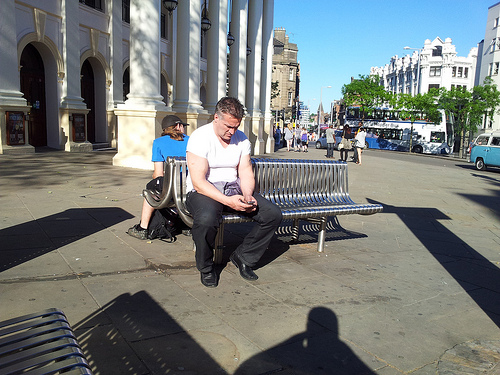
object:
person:
[128, 115, 191, 240]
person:
[338, 122, 351, 162]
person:
[324, 124, 338, 158]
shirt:
[183, 123, 249, 192]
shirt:
[151, 132, 190, 162]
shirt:
[354, 131, 367, 147]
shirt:
[324, 127, 335, 143]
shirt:
[301, 133, 307, 141]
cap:
[161, 114, 189, 126]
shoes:
[198, 262, 220, 288]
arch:
[16, 37, 64, 76]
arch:
[79, 54, 110, 83]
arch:
[122, 65, 135, 94]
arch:
[158, 70, 170, 102]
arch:
[197, 84, 209, 103]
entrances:
[78, 55, 108, 150]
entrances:
[121, 64, 134, 106]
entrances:
[159, 70, 169, 110]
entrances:
[199, 85, 209, 112]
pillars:
[114, 0, 177, 172]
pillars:
[166, 0, 204, 104]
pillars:
[204, 0, 232, 108]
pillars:
[227, 0, 252, 143]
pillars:
[251, 0, 265, 156]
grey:
[297, 193, 322, 204]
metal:
[314, 187, 339, 200]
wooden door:
[20, 49, 51, 150]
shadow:
[70, 288, 229, 373]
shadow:
[233, 305, 382, 373]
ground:
[1, 135, 498, 374]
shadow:
[0, 205, 135, 274]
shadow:
[363, 194, 499, 329]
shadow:
[453, 190, 500, 224]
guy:
[182, 96, 284, 289]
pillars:
[262, 6, 275, 151]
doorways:
[22, 37, 59, 153]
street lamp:
[403, 46, 421, 152]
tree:
[457, 78, 497, 157]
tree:
[392, 92, 439, 151]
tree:
[342, 75, 392, 132]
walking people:
[347, 124, 367, 164]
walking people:
[322, 124, 336, 156]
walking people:
[301, 125, 310, 150]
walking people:
[294, 123, 301, 151]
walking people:
[273, 123, 283, 146]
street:
[280, 144, 497, 277]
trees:
[439, 86, 462, 156]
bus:
[342, 104, 453, 156]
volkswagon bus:
[466, 129, 498, 170]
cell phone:
[247, 200, 256, 205]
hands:
[227, 194, 254, 214]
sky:
[271, 1, 491, 106]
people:
[354, 127, 367, 165]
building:
[0, 0, 274, 172]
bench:
[173, 159, 382, 263]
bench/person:
[125, 96, 383, 265]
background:
[273, 87, 432, 142]